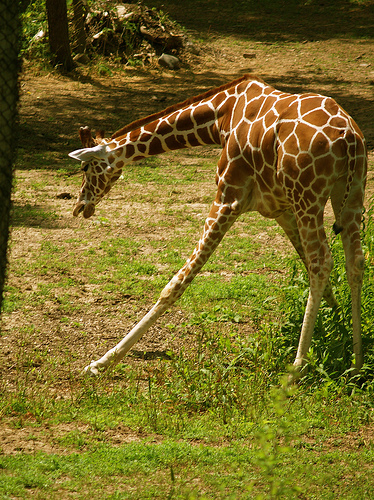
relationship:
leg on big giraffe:
[284, 215, 332, 370] [66, 66, 368, 382]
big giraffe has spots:
[66, 66, 368, 382] [291, 117, 319, 153]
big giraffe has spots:
[66, 66, 368, 382] [228, 116, 254, 152]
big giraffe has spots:
[66, 66, 368, 382] [294, 91, 330, 119]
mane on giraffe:
[110, 71, 269, 139] [12, 79, 365, 388]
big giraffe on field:
[66, 66, 368, 382] [14, 0, 373, 498]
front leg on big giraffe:
[84, 200, 230, 372] [66, 66, 368, 382]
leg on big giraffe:
[284, 215, 341, 308] [66, 66, 368, 382]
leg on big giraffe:
[332, 195, 371, 372] [66, 66, 368, 382]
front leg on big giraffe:
[92, 200, 230, 368] [66, 66, 368, 382]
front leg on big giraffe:
[269, 207, 341, 316] [66, 66, 368, 382]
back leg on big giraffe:
[291, 205, 333, 375] [66, 66, 368, 382]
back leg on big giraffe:
[339, 183, 373, 373] [66, 66, 368, 382]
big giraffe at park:
[66, 66, 368, 382] [19, 6, 362, 494]